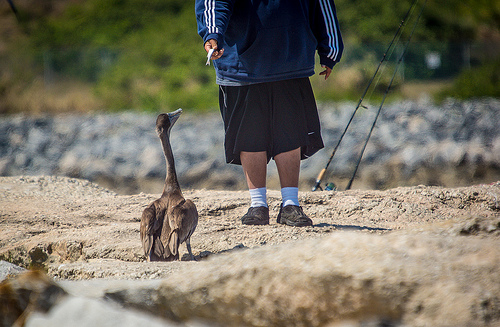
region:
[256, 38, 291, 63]
part of a pocket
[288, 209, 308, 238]
edge of a shoe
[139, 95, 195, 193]
the duck is looking up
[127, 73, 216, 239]
the duck is looking up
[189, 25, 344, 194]
the short is black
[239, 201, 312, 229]
Person is wearing shoes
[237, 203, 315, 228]
Person is wearing brown shoes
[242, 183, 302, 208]
Person is wearing socks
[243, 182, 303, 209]
Person is wearing white socks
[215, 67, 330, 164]
Person is wearing shorts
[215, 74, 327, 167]
Person is wearing black shorts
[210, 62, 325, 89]
Person is wearing an undershirt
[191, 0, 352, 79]
Person is wearing a sweatshirt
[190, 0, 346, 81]
Person is wearing a blue and white sweatshirt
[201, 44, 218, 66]
Person is holding a fish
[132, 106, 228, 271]
a duck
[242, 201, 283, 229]
person wearing shoes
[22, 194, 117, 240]
dirt on the ground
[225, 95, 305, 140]
black shorts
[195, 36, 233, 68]
a person holding an object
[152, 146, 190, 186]
the ducks neck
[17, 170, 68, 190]
rocks in the dirt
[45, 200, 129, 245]
the dirt is brown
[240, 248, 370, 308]
a big rock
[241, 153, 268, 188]
a persons leg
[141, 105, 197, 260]
bird is about to eat a fish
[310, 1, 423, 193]
two fishing poles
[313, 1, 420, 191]
fishing gear set in sand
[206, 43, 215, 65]
small fish is about to be fed to bird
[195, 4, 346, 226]
human feeding a bird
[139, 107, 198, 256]
brown bird with long neck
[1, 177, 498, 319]
sand covers the ground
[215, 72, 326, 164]
black baggy shorts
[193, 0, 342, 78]
coat indicates that it is cold weather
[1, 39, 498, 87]
fence or gate in the background